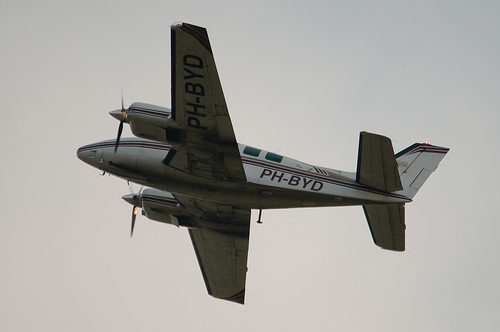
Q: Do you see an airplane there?
A: Yes, there is an airplane.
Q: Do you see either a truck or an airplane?
A: Yes, there is an airplane.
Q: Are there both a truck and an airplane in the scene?
A: No, there is an airplane but no trucks.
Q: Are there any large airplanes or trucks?
A: Yes, there is a large airplane.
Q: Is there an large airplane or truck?
A: Yes, there is a large airplane.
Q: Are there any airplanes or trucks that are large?
A: Yes, the airplane is large.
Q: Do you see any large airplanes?
A: Yes, there is a large airplane.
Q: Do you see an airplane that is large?
A: Yes, there is an airplane that is large.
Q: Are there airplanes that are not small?
A: Yes, there is a large airplane.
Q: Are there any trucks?
A: No, there are no trucks.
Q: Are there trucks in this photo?
A: No, there are no trucks.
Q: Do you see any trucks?
A: No, there are no trucks.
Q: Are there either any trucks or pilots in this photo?
A: No, there are no trucks or pilots.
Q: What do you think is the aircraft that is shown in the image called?
A: The aircraft is an airplane.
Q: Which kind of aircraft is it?
A: The aircraft is an airplane.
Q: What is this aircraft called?
A: This is an airplane.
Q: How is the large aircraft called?
A: The aircraft is an airplane.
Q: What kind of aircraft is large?
A: The aircraft is an airplane.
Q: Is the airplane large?
A: Yes, the airplane is large.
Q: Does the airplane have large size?
A: Yes, the airplane is large.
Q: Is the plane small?
A: No, the plane is large.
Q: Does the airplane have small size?
A: No, the airplane is large.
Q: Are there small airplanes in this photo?
A: No, there is an airplane but it is large.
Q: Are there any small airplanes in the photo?
A: No, there is an airplane but it is large.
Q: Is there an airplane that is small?
A: No, there is an airplane but it is large.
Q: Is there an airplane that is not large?
A: No, there is an airplane but it is large.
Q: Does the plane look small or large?
A: The plane is large.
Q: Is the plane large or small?
A: The plane is large.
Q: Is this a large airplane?
A: Yes, this is a large airplane.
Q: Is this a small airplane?
A: No, this is a large airplane.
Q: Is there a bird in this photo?
A: No, there are no birds.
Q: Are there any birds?
A: No, there are no birds.